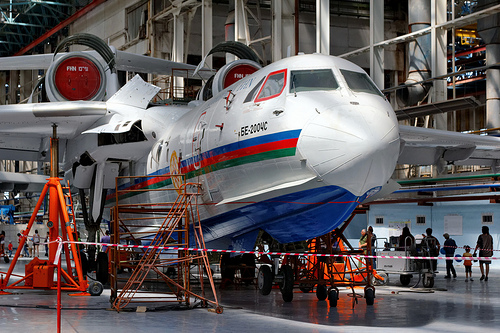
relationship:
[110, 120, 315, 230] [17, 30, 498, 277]
stripe on airplane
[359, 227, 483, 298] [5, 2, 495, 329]
people in building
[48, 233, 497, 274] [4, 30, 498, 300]
rope around airplane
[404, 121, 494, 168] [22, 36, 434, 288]
wing on airplane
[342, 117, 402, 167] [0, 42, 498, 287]
plane nose of plane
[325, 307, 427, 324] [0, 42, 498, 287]
shadow under plane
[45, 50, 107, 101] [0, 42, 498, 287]
engine of plane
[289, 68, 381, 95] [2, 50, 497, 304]
cockpit of plane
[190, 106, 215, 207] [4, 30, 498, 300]
door on airplane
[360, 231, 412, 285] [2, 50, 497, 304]
cart by plane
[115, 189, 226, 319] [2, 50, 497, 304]
case next to plane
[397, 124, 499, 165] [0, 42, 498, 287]
wing of plane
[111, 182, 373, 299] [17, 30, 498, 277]
blue bottom of airplane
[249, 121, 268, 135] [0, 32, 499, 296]
letter on airplane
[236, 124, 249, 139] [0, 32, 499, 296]
letters on airplane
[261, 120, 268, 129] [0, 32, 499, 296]
letter on airplane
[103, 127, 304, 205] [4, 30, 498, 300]
stripe on airplane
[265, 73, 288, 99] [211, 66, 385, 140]
window on cockpit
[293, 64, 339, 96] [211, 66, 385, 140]
window on cockpit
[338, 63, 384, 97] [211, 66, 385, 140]
window on cockpit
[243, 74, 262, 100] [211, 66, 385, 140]
window on cockpit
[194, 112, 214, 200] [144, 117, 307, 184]
door on side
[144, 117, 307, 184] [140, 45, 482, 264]
side of airplane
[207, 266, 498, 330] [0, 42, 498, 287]
shadow of plane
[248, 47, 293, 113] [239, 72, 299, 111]
red border around window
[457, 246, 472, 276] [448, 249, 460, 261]
kid holding balloon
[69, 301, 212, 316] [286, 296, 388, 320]
black wires on floor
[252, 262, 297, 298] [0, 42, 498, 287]
front wheels in front of plane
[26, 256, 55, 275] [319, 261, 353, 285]
tip of orange box